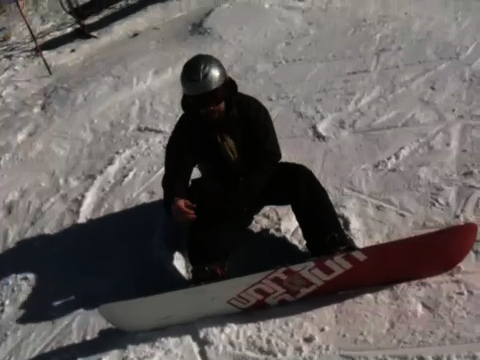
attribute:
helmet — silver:
[161, 56, 248, 106]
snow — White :
[250, 32, 471, 138]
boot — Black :
[300, 229, 360, 253]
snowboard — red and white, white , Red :
[96, 220, 477, 335]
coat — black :
[154, 107, 272, 209]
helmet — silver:
[156, 51, 254, 109]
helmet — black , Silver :
[183, 57, 225, 99]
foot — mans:
[310, 236, 362, 256]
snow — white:
[312, 20, 435, 164]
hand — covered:
[201, 128, 275, 188]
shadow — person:
[9, 195, 162, 337]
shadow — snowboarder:
[2, 178, 180, 326]